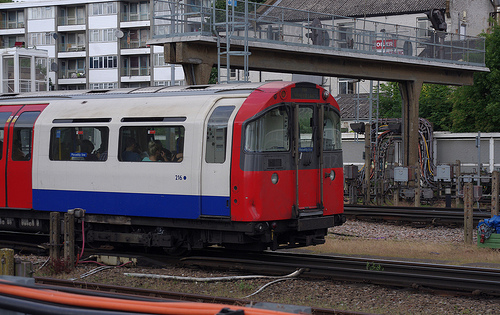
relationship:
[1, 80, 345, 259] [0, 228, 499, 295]
train on tracks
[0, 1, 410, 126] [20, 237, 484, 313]
building behind tracks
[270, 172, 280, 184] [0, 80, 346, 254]
headlight on front of car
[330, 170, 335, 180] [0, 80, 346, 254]
headlight on front of car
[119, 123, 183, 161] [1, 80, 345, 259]
passengers in train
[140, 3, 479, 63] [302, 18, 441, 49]
fencing along balcony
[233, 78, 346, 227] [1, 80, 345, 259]
red paint on train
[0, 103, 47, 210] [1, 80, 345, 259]
red paint on train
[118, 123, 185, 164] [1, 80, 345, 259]
window on train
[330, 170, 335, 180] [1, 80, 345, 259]
headlight on train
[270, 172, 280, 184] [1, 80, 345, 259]
headlight on train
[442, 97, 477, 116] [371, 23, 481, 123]
leaves on trees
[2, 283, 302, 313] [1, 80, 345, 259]
tubes near train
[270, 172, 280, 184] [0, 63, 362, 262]
headlight on train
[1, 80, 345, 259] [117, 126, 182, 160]
train has window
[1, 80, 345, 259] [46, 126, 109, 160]
train has window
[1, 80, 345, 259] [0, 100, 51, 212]
train has door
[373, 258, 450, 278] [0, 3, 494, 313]
track in photo